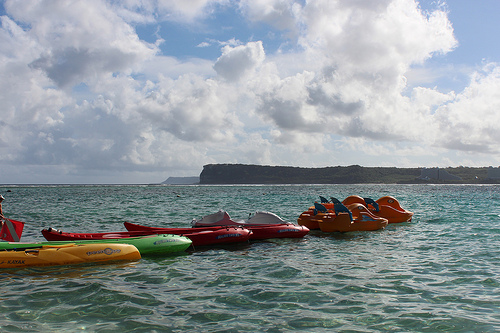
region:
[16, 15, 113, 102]
white clouds in blue sky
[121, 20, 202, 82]
white clouds in blue sky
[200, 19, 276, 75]
white clouds in blue sky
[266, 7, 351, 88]
white clouds in blue sky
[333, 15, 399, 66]
white clouds in blue sky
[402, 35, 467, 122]
white clouds in blue sky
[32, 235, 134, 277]
yellow colored raft in water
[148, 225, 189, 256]
green colored raft in water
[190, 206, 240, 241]
red colored raft in water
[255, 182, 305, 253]
red colored raft in water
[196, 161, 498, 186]
Land in the background.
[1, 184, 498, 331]
Blue water in the forefront.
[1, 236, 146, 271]
Yellow water craft on the water.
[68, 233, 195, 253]
Green craft on the water.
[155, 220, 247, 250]
Red craft on the water.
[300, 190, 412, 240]
Orange paddle boats on the water.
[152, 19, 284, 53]
Blue sky behind the clouds.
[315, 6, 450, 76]
White cloud in the background.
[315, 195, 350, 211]
Blue seats on paddle boat.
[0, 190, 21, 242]
Person holding red material in the background.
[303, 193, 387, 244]
red rube ride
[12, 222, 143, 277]
orange raft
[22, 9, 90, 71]
white clouds in blue sky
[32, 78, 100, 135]
white clouds in blue sky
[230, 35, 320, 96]
white clouds in blue sky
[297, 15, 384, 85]
white clouds in blue sky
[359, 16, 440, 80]
white clouds in blue sky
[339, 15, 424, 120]
white clouds in blue sky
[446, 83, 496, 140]
white clouds in blue sky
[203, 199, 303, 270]
red uvbe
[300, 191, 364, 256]
red tube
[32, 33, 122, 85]
white clouds in blue sky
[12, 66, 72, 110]
white clouds in blue sky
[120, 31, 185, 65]
white clouds in blue sky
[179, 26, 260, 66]
white clouds in blue sky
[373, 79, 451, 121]
white clouds in blue sky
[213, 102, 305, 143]
white clouds in blue sky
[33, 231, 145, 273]
yellow tube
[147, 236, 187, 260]
green tube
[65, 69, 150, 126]
white clouds in blue sky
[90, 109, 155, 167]
white clouds in blue sky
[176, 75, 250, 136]
white clouds in blue sky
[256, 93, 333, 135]
white clouds in blue sky